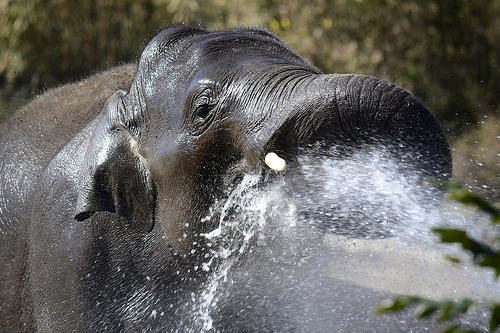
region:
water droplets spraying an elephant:
[380, 147, 457, 235]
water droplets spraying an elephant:
[301, 152, 378, 226]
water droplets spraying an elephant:
[230, 174, 300, 234]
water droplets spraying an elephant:
[207, 242, 268, 320]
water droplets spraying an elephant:
[281, 259, 341, 320]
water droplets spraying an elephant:
[361, 230, 434, 297]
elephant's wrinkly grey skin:
[237, 52, 320, 127]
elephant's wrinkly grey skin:
[112, 84, 149, 126]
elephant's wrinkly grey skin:
[112, 259, 162, 329]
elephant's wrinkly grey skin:
[210, 35, 295, 85]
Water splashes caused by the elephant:
[160, 135, 492, 330]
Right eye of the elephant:
[180, 85, 221, 135]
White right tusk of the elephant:
[260, 145, 290, 170]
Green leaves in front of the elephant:
[370, 170, 490, 330]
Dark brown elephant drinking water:
[0, 20, 455, 325]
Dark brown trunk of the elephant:
[275, 70, 455, 240]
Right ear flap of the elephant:
[70, 85, 155, 232]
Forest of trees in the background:
[0, 0, 495, 140]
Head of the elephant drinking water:
[73, 21, 374, 261]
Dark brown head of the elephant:
[138, 20, 289, 59]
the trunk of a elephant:
[237, 52, 460, 218]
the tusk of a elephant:
[230, 124, 309, 220]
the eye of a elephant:
[181, 86, 236, 141]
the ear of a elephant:
[36, 73, 209, 244]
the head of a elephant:
[58, 17, 331, 257]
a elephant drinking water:
[149, 39, 464, 299]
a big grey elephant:
[20, 0, 457, 252]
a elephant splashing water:
[103, 39, 449, 291]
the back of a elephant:
[42, 25, 439, 281]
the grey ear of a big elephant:
[48, 79, 200, 238]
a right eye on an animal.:
[179, 65, 235, 139]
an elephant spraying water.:
[255, 68, 468, 272]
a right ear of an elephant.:
[60, 105, 163, 250]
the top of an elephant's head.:
[101, 22, 294, 123]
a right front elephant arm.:
[26, 112, 186, 331]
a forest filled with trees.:
[0, 0, 497, 223]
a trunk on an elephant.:
[251, 49, 455, 197]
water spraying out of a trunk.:
[157, 157, 498, 328]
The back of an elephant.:
[0, 46, 160, 196]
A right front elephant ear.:
[61, 98, 175, 237]